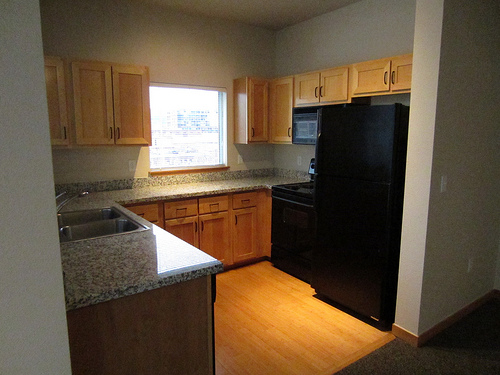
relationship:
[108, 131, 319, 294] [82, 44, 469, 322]
kitchen in house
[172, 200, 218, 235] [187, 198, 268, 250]
handles on cabinets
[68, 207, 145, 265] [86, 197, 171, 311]
sink in counter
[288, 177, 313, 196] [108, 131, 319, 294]
stove in kitchen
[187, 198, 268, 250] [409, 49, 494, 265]
cabinets on wall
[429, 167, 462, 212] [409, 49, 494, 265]
switch on wall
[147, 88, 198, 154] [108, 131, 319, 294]
window in kitchen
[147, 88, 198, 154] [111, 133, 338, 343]
window in ktichen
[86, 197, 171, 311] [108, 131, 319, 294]
counter in kitchen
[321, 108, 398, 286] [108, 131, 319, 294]
refrigerator in kitchen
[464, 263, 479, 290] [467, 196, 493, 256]
plug in hallway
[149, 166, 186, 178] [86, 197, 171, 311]
sunlight on counter